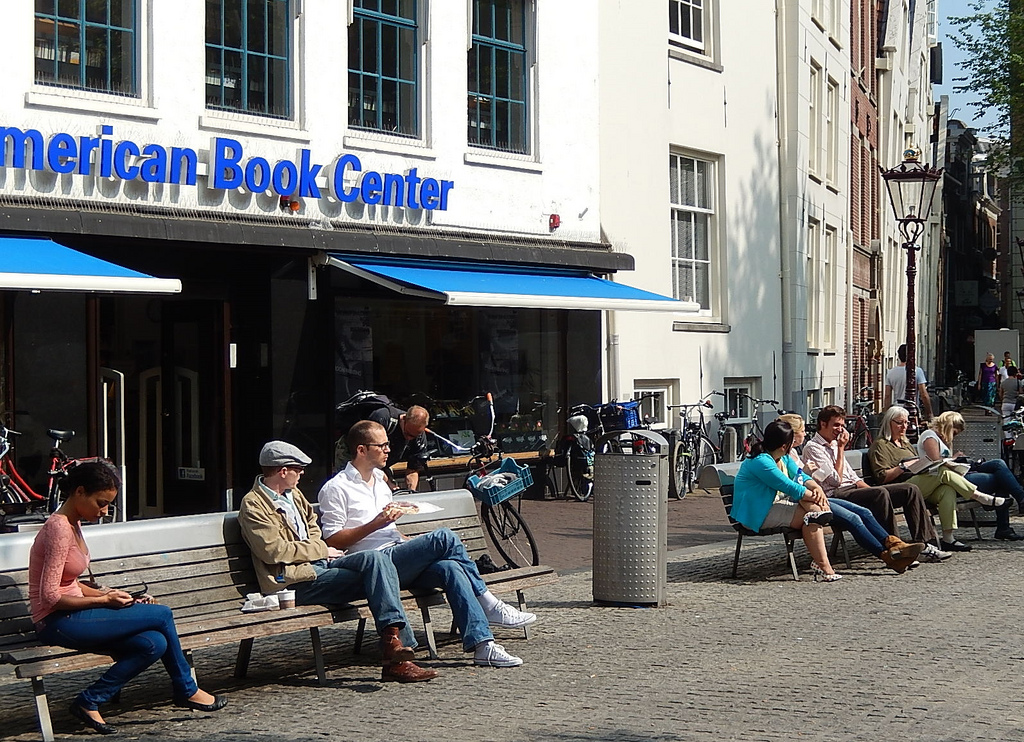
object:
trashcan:
[592, 429, 668, 608]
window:
[670, 144, 722, 323]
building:
[599, 0, 849, 493]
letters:
[79, 136, 101, 175]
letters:
[99, 126, 112, 179]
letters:
[113, 140, 140, 180]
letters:
[140, 144, 167, 183]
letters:
[169, 147, 197, 186]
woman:
[27, 463, 230, 736]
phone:
[129, 580, 149, 597]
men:
[236, 439, 441, 682]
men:
[318, 420, 537, 669]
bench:
[0, 489, 559, 742]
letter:
[214, 137, 244, 190]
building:
[0, 0, 636, 531]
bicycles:
[392, 392, 539, 569]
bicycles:
[564, 394, 662, 502]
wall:
[269, 263, 598, 500]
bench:
[5, 447, 552, 737]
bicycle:
[0, 425, 117, 525]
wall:
[0, 234, 90, 535]